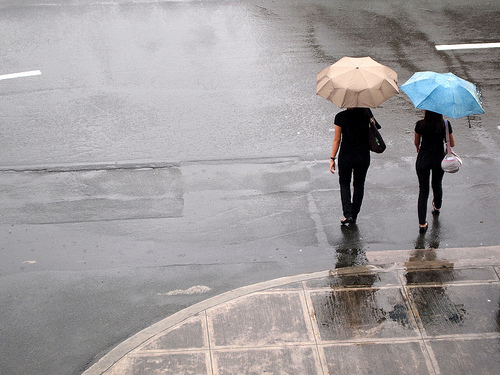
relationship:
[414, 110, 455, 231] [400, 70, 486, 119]
pedestrian carrying umbrella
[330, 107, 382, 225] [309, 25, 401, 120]
pedestrians holding umbrella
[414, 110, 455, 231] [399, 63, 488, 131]
pedestrian holding umbrella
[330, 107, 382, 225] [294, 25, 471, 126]
pedestrians holding umbrellas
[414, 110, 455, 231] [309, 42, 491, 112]
pedestrian are holding umbrellas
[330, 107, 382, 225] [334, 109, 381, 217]
pedestrians wearing clothes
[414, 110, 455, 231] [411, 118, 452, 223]
pedestrian wearing clothes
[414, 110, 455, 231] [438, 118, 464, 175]
pedestrian wearing purse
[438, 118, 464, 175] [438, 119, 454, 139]
purse on shoulder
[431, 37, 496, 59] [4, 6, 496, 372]
line on road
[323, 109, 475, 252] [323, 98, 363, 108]
pedestrians holding umbrellas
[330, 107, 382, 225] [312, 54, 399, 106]
pedestrians holding umbrella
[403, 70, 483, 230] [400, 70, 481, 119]
pedestrian holding umbrella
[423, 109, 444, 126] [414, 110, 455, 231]
head of a pedestrian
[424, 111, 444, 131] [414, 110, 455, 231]
hair of a pedestrian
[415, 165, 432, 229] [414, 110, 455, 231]
leg of a pedestrian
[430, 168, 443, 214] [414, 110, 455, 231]
leg of a pedestrian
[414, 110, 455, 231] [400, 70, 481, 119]
pedestrian holding umbrella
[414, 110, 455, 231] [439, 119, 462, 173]
pedestrian holds purse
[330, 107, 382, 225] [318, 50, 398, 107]
pedestrians holds umbrella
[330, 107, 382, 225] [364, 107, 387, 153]
pedestrians holds purse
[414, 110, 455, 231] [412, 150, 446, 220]
pedestrian wearing pants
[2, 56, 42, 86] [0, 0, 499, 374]
lines are on street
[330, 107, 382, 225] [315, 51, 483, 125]
pedestrians holding umbrellas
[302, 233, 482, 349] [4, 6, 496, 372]
reflection on road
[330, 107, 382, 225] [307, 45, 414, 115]
pedestrians carrying umbrella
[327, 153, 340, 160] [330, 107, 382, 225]
watch on pedestrians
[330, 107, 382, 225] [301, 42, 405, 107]
pedestrians carrying umbrella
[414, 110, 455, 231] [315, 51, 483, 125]
pedestrian holding umbrellas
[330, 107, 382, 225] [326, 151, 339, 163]
pedestrians wearing wristwatch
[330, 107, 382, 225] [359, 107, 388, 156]
pedestrians carrying purse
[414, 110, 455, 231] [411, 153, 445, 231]
pedestrian wearing pants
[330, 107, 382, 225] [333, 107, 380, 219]
pedestrians in black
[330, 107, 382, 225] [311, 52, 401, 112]
pedestrians holding umbrella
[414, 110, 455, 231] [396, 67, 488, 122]
pedestrian holding umbrella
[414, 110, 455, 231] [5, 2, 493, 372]
pedestrian crossing street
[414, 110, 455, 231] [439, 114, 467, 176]
pedestrian holding bag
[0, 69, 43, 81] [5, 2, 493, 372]
lines on street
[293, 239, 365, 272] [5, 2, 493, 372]
puddle on street